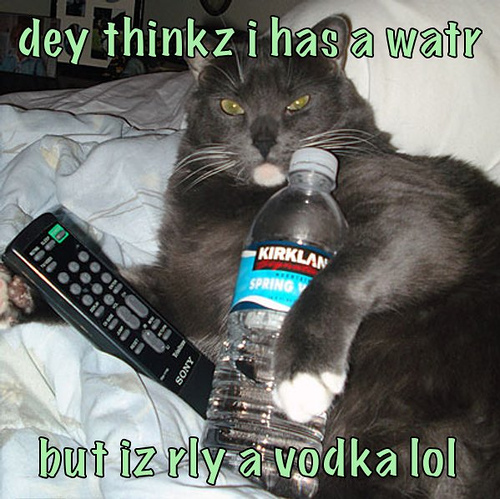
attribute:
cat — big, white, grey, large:
[199, 54, 422, 281]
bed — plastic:
[63, 86, 138, 200]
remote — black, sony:
[30, 213, 189, 381]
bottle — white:
[260, 197, 328, 319]